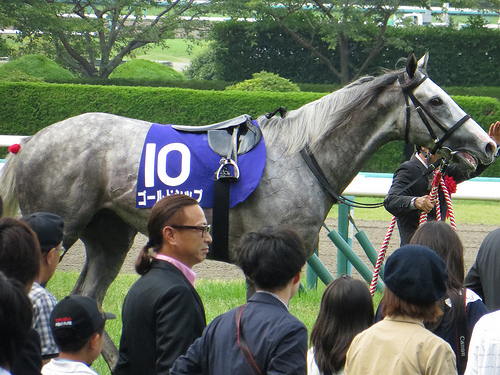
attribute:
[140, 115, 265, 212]
saddle — black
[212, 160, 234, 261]
strap — black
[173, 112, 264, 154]
english saddle — black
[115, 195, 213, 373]
man — Japanese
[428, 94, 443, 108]
eye — black, small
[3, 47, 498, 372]
horse — grey, white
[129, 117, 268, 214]
saddle blanket — blue, white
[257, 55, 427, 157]
mane — white, silvery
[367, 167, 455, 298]
rope — red, white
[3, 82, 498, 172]
hedge — long, green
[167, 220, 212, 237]
glasses — eye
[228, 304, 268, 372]
strap — leather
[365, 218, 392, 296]
rope — white, red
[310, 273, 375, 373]
hair — dark, brown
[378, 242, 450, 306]
beret — black, blue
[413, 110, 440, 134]
halter — skinny, black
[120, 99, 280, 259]
harness — black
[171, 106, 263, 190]
saddle — black, gray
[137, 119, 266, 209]
pad — blue, white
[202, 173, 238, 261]
strap — black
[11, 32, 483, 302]
horse — silver, black